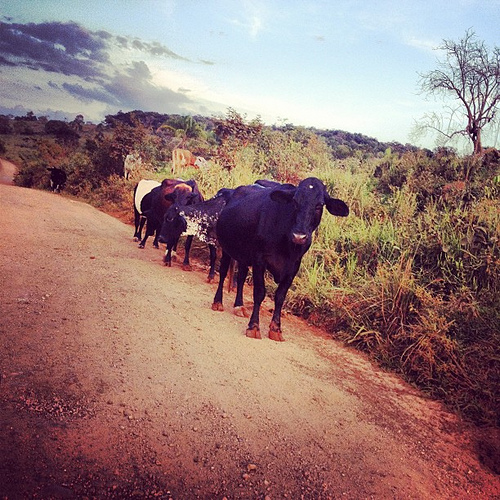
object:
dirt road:
[0, 156, 500, 498]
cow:
[165, 179, 282, 291]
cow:
[211, 177, 349, 341]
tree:
[408, 25, 499, 151]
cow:
[136, 177, 204, 272]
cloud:
[43, 79, 61, 91]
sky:
[0, 0, 500, 156]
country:
[0, 109, 500, 498]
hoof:
[243, 322, 261, 338]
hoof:
[265, 326, 284, 343]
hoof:
[232, 305, 250, 317]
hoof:
[209, 301, 227, 312]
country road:
[0, 159, 500, 498]